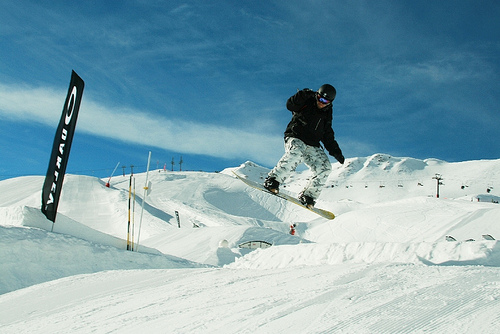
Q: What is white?
A: The snow.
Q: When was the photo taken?
A: Day time.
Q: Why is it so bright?
A: Sun light.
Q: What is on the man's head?
A: A helmet.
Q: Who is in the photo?
A: A man.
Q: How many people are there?
A: One.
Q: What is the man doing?
A: Snowboarding.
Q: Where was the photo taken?
A: On a ski slope.